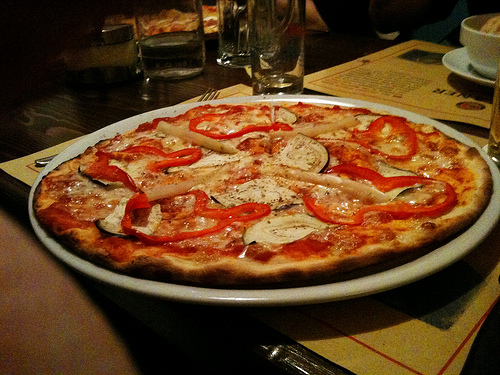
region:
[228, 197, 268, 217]
red peppers on the pizza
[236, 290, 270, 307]
the plate is white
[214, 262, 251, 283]
crust of the pizzs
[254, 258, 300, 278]
the crust is brown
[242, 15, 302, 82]
a clear glass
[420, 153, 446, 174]
cheese on the pizza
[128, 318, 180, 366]
a dark shadow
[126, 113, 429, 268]
a pizza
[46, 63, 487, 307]
An extra large pizza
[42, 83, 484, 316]
a thin crust pizza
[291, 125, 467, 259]
red pepper on a pizza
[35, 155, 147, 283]
burnt pizza crust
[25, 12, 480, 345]
pizza on a white plate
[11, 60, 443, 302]
a fork to help eat pizza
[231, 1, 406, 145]
a clear empty drinking glass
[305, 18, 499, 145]
a table placemat under a bowl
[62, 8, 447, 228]
a second pizza at the same table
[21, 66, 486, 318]
Pizza on a table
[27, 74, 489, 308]
The pizza is round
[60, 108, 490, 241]
Red pepper slices on the pizza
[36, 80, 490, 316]
The plate is white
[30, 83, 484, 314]
The plate is round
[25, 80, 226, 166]
Fork to the left of the plate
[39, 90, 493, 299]
The pizza is intact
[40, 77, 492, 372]
Yellow place mat on the table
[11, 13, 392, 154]
The table is made of wood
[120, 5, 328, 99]
Glasses on the table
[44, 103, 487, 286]
Whole pizza on a tray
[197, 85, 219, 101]
Fork tines near pizza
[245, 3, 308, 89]
Drinking glass near pizza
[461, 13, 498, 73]
White bowl on a plate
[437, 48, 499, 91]
White plate with a bowl on it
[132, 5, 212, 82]
Drinking glass on a table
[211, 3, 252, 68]
Drinking glass on a table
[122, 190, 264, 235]
Sliced red pepper on pizza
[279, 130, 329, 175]
Vegetable topping on a pizza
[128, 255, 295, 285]
Burned crust on pizza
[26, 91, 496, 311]
whole pizza on round plate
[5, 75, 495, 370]
white plate on brown place mat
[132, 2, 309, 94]
clear glasses on wooden table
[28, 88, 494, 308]
A pizza.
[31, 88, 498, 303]
A whole pizza on a grey tray.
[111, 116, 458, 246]
Red peppers on the pizza.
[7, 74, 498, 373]
A paper place mat under the pizza.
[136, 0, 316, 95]
Empty glasses on the table.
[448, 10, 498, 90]
A white bowl on the table.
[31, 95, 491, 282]
The pizza has not been cut.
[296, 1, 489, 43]
A person sitting at the table.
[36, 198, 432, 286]
A burnt edge on the pizza.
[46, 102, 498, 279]
A vegetable pizza.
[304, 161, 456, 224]
The largest red pepper on the pizza.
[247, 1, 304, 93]
Clear glass directly above the pizza.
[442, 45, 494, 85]
Smaller round white plate with a bowl on top.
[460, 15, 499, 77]
Small white bowl past the pizza.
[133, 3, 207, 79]
Thicker clear glass with visible water inside.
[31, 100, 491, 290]
A round pizza with cheese and red peppers.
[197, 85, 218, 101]
Four silver fork tines past the pizza